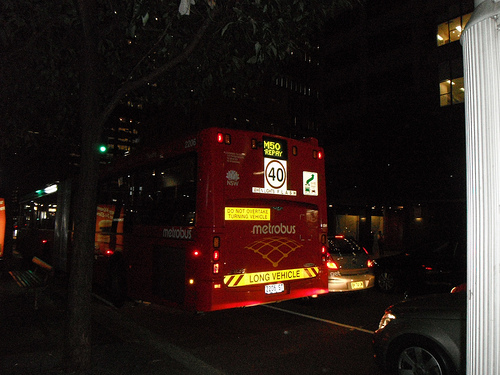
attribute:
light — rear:
[208, 246, 227, 263]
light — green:
[92, 144, 113, 154]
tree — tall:
[12, 11, 154, 373]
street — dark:
[109, 271, 376, 370]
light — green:
[92, 146, 112, 160]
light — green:
[27, 184, 49, 197]